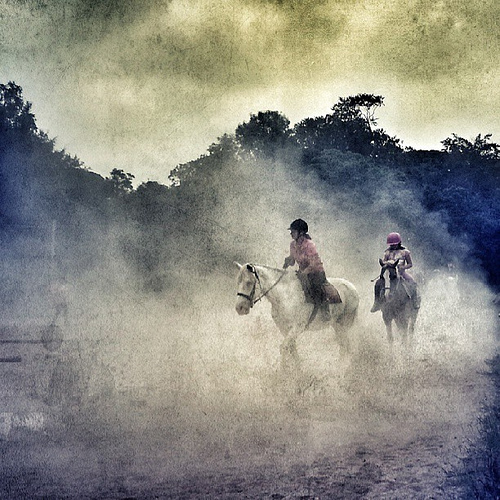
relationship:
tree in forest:
[330, 91, 385, 133] [4, 5, 499, 497]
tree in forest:
[330, 91, 385, 133] [6, 66, 496, 316]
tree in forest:
[289, 95, 439, 208] [6, 66, 496, 316]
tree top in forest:
[176, 132, 236, 182] [31, 141, 351, 214]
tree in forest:
[330, 91, 385, 133] [66, 171, 498, 219]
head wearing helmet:
[283, 215, 313, 240] [283, 217, 313, 235]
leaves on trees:
[243, 93, 385, 156] [0, 80, 499, 287]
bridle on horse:
[232, 261, 294, 312] [190, 229, 361, 388]